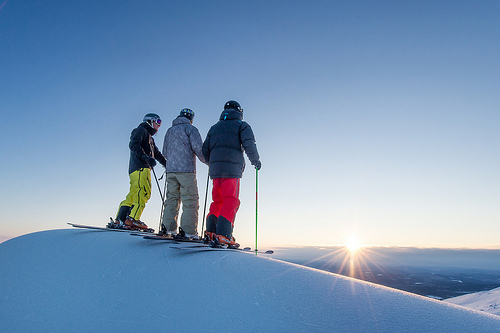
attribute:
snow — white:
[190, 254, 364, 324]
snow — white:
[192, 257, 346, 323]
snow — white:
[233, 283, 329, 314]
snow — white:
[244, 285, 341, 310]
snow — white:
[250, 277, 358, 319]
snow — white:
[189, 260, 338, 318]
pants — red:
[210, 178, 243, 230]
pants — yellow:
[114, 165, 150, 212]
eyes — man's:
[148, 121, 162, 131]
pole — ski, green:
[246, 162, 262, 248]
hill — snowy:
[310, 242, 431, 312]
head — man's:
[215, 99, 246, 123]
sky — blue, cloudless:
[233, 0, 404, 108]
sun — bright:
[339, 228, 366, 258]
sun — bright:
[341, 224, 370, 251]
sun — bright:
[341, 223, 364, 253]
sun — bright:
[341, 226, 364, 247]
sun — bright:
[337, 221, 366, 250]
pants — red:
[206, 177, 244, 217]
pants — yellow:
[117, 172, 153, 215]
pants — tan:
[159, 170, 204, 235]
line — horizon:
[15, 232, 498, 261]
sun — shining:
[335, 222, 369, 252]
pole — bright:
[248, 164, 264, 254]